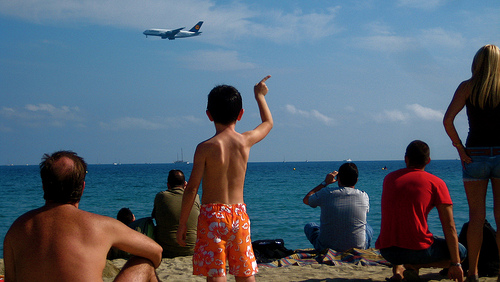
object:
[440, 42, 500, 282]
woman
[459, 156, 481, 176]
pocket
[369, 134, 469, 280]
man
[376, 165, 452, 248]
red shirt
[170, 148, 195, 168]
boat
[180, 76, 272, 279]
boy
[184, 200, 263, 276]
swimsuit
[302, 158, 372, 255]
man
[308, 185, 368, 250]
shirt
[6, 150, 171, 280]
man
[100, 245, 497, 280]
sand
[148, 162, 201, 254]
man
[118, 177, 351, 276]
beach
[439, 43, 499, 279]
lady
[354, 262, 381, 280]
sand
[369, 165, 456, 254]
shirt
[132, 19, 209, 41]
airplane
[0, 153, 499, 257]
water